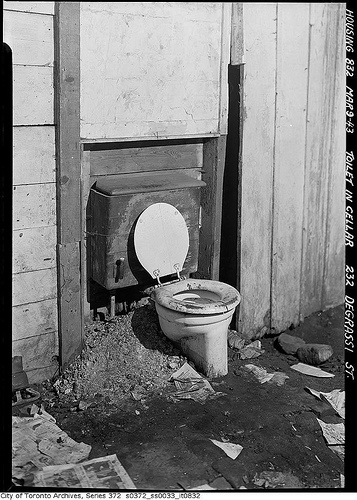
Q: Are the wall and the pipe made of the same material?
A: No, the wall is made of wood and the pipe is made of metal.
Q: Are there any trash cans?
A: No, there are no trash cans.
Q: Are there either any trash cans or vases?
A: No, there are no trash cans or vases.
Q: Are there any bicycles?
A: No, there are no bicycles.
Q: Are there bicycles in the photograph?
A: No, there are no bicycles.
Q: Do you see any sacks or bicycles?
A: No, there are no bicycles or sacks.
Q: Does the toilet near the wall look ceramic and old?
A: Yes, the toilet is ceramic and old.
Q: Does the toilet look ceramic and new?
A: No, the toilet is ceramic but old.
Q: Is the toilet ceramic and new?
A: No, the toilet is ceramic but old.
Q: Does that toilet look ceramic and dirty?
A: Yes, the toilet is ceramic and dirty.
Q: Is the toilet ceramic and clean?
A: No, the toilet is ceramic but dirty.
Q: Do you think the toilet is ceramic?
A: Yes, the toilet is ceramic.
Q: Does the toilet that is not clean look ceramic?
A: Yes, the toilet is ceramic.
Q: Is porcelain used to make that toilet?
A: Yes, the toilet is made of porcelain.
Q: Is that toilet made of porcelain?
A: Yes, the toilet is made of porcelain.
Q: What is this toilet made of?
A: The toilet is made of porcelain.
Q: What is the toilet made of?
A: The toilet is made of porcelain.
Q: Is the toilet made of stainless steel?
A: No, the toilet is made of porcelain.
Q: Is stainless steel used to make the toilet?
A: No, the toilet is made of porcelain.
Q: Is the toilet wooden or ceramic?
A: The toilet is ceramic.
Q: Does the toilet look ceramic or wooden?
A: The toilet is ceramic.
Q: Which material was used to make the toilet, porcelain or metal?
A: The toilet is made of porcelain.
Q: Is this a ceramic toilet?
A: Yes, this is a ceramic toilet.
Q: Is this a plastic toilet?
A: No, this is a ceramic toilet.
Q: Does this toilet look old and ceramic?
A: Yes, the toilet is old and ceramic.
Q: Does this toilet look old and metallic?
A: No, the toilet is old but ceramic.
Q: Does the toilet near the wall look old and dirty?
A: Yes, the toilet is old and dirty.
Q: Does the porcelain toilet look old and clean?
A: No, the toilet is old but dirty.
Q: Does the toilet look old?
A: Yes, the toilet is old.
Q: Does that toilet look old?
A: Yes, the toilet is old.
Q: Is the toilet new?
A: No, the toilet is old.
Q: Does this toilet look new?
A: No, the toilet is old.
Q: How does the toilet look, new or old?
A: The toilet is old.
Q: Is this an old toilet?
A: Yes, this is an old toilet.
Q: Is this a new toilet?
A: No, this is an old toilet.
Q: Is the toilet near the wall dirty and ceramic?
A: Yes, the toilet is dirty and ceramic.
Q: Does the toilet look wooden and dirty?
A: No, the toilet is dirty but ceramic.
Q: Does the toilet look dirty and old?
A: Yes, the toilet is dirty and old.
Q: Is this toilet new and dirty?
A: No, the toilet is dirty but old.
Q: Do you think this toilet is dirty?
A: Yes, the toilet is dirty.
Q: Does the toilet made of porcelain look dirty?
A: Yes, the toilet is dirty.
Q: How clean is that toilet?
A: The toilet is dirty.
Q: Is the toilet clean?
A: No, the toilet is dirty.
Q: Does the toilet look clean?
A: No, the toilet is dirty.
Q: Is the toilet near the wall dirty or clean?
A: The toilet is dirty.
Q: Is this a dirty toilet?
A: Yes, this is a dirty toilet.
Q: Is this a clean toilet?
A: No, this is a dirty toilet.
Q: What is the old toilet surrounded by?
A: The toilet is surrounded by the dirt.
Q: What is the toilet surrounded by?
A: The toilet is surrounded by the dirt.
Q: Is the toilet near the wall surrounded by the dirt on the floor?
A: Yes, the toilet is surrounded by the dirt.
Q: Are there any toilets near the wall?
A: Yes, there is a toilet near the wall.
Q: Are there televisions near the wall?
A: No, there is a toilet near the wall.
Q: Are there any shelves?
A: No, there are no shelves.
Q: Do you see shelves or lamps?
A: No, there are no shelves or lamps.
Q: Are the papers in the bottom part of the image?
A: Yes, the papers are in the bottom of the image.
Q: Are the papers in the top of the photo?
A: No, the papers are in the bottom of the image.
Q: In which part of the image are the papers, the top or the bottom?
A: The papers are in the bottom of the image.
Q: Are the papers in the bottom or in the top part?
A: The papers are in the bottom of the image.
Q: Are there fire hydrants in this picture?
A: No, there are no fire hydrants.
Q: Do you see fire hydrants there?
A: No, there are no fire hydrants.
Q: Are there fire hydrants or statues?
A: No, there are no fire hydrants or statues.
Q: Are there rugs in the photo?
A: No, there are no rugs.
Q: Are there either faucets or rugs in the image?
A: No, there are no rugs or faucets.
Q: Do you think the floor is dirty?
A: Yes, the floor is dirty.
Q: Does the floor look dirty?
A: Yes, the floor is dirty.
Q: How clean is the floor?
A: The floor is dirty.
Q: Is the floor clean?
A: No, the floor is dirty.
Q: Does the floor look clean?
A: No, the floor is dirty.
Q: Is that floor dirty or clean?
A: The floor is dirty.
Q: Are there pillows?
A: No, there are no pillows.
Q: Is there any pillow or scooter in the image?
A: No, there are no pillows or scooters.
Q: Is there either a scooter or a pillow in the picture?
A: No, there are no pillows or scooters.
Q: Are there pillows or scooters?
A: No, there are no pillows or scooters.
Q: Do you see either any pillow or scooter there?
A: No, there are no pillows or scooters.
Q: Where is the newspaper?
A: The newspaper is on the floor.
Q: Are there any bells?
A: No, there are no bells.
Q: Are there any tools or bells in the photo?
A: No, there are no bells or tools.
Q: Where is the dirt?
A: The dirt is on the floor.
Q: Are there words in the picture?
A: Yes, there are words.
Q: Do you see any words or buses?
A: Yes, there are words.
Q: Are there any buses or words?
A: Yes, there are words.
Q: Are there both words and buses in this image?
A: No, there are words but no buses.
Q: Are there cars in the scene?
A: No, there are no cars.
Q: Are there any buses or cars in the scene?
A: No, there are no cars or buses.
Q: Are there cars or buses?
A: No, there are no cars or buses.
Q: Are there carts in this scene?
A: No, there are no carts.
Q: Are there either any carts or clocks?
A: No, there are no carts or clocks.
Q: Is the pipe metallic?
A: Yes, the pipe is metallic.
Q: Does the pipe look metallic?
A: Yes, the pipe is metallic.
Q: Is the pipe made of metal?
A: Yes, the pipe is made of metal.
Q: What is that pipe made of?
A: The pipe is made of metal.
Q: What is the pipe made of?
A: The pipe is made of metal.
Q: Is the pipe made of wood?
A: No, the pipe is made of metal.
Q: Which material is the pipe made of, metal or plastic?
A: The pipe is made of metal.